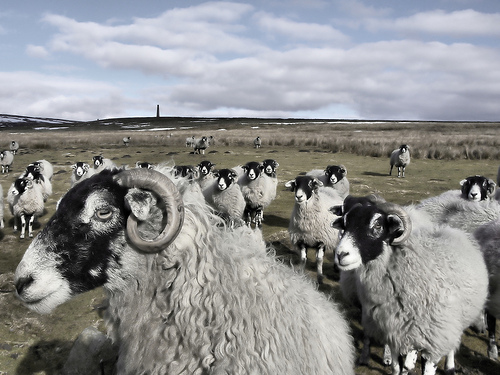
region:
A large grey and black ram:
[36, 189, 312, 374]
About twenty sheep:
[8, 140, 498, 372]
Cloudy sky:
[32, 2, 498, 115]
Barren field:
[6, 116, 494, 163]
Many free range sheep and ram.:
[0, 137, 497, 371]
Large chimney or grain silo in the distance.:
[148, 94, 168, 122]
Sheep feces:
[51, 146, 180, 157]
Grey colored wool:
[130, 309, 352, 372]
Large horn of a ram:
[115, 166, 187, 257]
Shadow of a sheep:
[16, 326, 102, 373]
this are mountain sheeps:
[58, 138, 413, 262]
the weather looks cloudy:
[66, 78, 179, 96]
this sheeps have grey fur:
[83, 168, 308, 373]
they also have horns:
[118, 142, 246, 303]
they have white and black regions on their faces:
[343, 218, 399, 285]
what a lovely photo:
[41, 131, 429, 361]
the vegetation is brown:
[41, 123, 200, 134]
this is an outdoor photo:
[29, 128, 314, 350]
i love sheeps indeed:
[55, 174, 490, 355]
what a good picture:
[28, 133, 389, 367]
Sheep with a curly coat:
[11, 165, 356, 373]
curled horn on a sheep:
[111, 164, 186, 255]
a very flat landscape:
[0, 115, 496, 217]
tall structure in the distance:
[154, 102, 161, 117]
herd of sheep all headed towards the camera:
[1, 132, 498, 372]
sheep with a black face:
[10, 167, 354, 373]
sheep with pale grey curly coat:
[10, 161, 355, 373]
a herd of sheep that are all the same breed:
[1, 133, 497, 370]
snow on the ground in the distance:
[0, 112, 499, 133]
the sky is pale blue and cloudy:
[1, 0, 499, 125]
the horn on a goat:
[115, 163, 181, 252]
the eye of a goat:
[96, 202, 113, 224]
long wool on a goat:
[188, 267, 288, 333]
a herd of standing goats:
[60, 145, 425, 307]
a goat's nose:
[11, 268, 41, 290]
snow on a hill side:
[123, 118, 151, 131]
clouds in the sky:
[224, 43, 269, 71]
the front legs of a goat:
[396, 160, 408, 174]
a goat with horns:
[10, 167, 285, 362]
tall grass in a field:
[296, 130, 356, 149]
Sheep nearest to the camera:
[9, 161, 358, 373]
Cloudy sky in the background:
[1, 1, 499, 121]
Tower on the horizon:
[148, 100, 165, 117]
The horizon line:
[1, 108, 496, 125]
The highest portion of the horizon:
[1, 108, 66, 125]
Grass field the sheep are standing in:
[1, 121, 499, 373]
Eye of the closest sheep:
[93, 203, 115, 228]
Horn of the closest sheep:
[110, 166, 187, 256]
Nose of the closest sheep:
[11, 270, 39, 295]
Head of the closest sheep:
[9, 164, 185, 318]